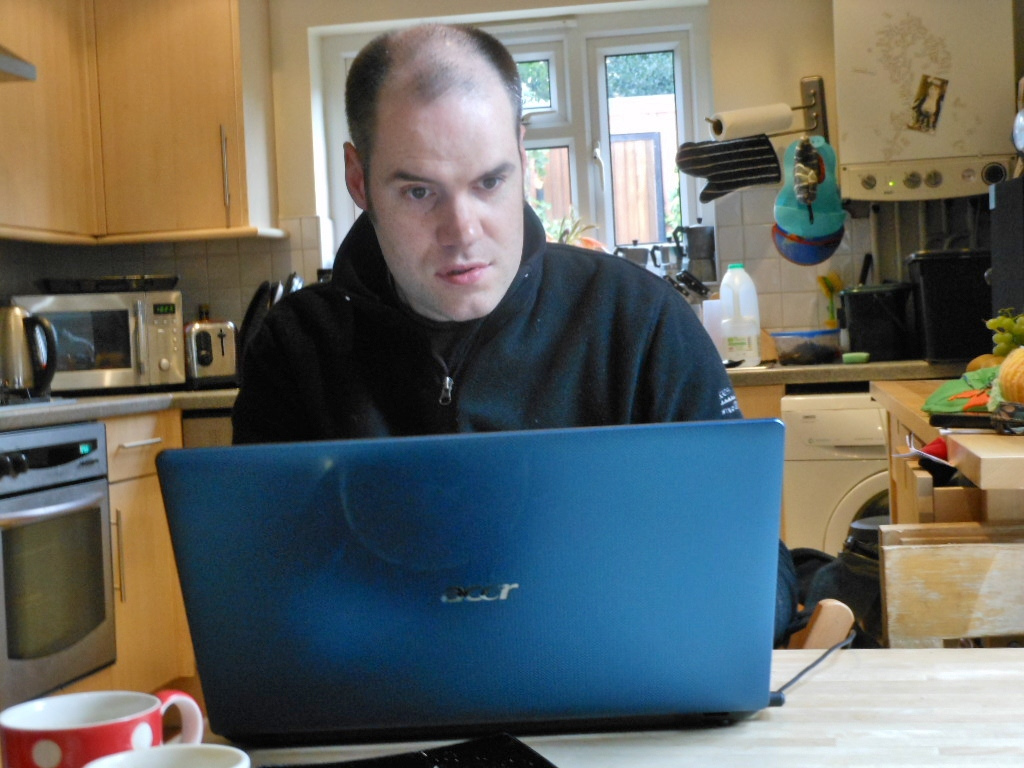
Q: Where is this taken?
A: In a kitchen.